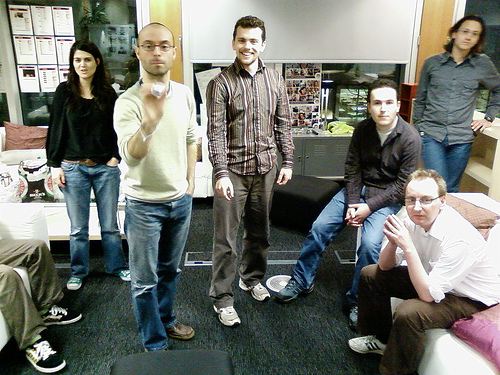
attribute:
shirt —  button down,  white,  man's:
[401, 213, 498, 308]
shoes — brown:
[144, 316, 195, 347]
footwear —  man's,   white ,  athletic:
[201, 269, 298, 333]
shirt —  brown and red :
[209, 46, 323, 193]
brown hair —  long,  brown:
[434, 12, 486, 67]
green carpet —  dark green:
[25, 203, 377, 373]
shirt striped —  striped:
[213, 72, 303, 184]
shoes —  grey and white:
[214, 302, 252, 325]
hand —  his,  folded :
[384, 213, 415, 245]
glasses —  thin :
[401, 193, 442, 206]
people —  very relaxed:
[51, 14, 492, 374]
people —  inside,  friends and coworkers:
[2, 14, 498, 374]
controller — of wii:
[151, 81, 165, 101]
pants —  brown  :
[207, 157, 277, 294]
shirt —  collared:
[205, 56, 296, 175]